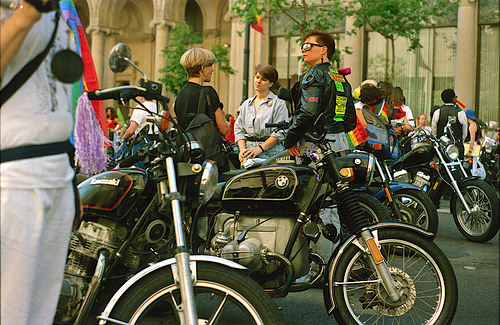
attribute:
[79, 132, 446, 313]
motorcycle — black, in foreground, kawasaki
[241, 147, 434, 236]
motorcycle — in background, bmw, blue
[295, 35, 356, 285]
rider — talking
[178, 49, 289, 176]
women — talking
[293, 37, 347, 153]
woman — standing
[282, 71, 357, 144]
jacket — leather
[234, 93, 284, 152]
shirt — blue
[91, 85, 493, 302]
motorcycles — parked, in large group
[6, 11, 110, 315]
woman — in foreground